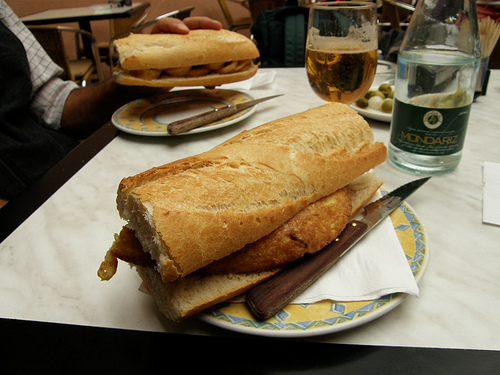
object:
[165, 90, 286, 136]
knife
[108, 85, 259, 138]
plate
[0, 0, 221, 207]
man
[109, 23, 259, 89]
sandwich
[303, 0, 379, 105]
glass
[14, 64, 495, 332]
paper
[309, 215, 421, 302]
napkin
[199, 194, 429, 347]
plate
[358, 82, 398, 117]
olives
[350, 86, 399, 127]
plate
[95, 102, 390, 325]
sandwich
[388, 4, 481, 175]
bottle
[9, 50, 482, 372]
table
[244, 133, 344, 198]
crust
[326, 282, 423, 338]
edge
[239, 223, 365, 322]
handle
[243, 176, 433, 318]
knife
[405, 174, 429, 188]
tip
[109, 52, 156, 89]
edge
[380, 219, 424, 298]
edge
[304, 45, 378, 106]
beverage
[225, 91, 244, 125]
design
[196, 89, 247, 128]
designs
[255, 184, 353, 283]
meat